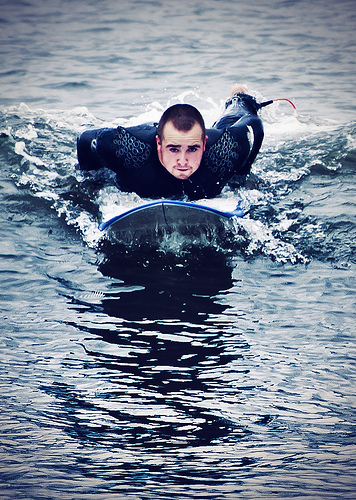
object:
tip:
[147, 194, 182, 214]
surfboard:
[97, 195, 243, 250]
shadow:
[103, 244, 239, 460]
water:
[0, 1, 354, 498]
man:
[74, 83, 264, 205]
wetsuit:
[76, 92, 264, 199]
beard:
[169, 164, 195, 182]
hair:
[157, 103, 206, 144]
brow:
[165, 142, 182, 150]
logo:
[88, 136, 96, 150]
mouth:
[176, 165, 191, 173]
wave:
[9, 101, 111, 249]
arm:
[76, 124, 129, 176]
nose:
[177, 151, 188, 167]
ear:
[154, 135, 161, 157]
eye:
[186, 145, 196, 155]